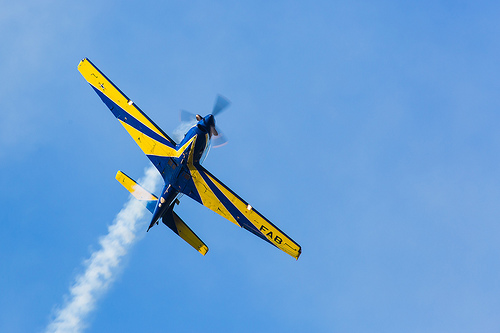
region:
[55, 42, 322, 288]
airplane in sky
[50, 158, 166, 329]
white smoke emitting from plane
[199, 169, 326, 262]
wing on plane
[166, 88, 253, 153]
propeller on front of plane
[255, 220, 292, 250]
word on plane wing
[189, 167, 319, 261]
stripes on plane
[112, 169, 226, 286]
tail of plane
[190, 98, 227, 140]
nose of plane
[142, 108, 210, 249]
body of plane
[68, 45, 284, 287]
a plane that is flying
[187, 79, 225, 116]
the blade of a propeller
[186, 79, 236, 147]
the propeller on a plane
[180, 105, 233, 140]
the nose of a plane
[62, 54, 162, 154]
the right wing of a plane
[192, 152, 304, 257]
the left wing of a plane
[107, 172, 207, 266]
the tail wing of a plane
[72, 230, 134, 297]
a bunch of white smoke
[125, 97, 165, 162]
the stripes on a plane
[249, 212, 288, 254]
the logo of a plane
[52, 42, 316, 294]
yellow and blue plane doing trick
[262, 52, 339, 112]
white clouds in blue sky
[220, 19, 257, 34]
white clouds in blue sky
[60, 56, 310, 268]
yellow and blue plane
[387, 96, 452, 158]
white clouds in blue sky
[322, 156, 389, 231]
white clouds in blue sky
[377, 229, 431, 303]
white clouds in blue sky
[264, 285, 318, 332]
white clouds in blue sky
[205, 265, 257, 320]
white clouds in blue sky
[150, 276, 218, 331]
white clouds in blue sky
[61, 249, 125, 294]
smoke from plane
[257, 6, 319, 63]
white clouds in blue sky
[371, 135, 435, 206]
white clouds in blue sky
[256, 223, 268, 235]
black letter on plane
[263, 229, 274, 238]
black letter on plane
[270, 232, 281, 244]
black letter on plane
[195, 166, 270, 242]
blue stripe on plane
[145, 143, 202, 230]
blue stripe on plane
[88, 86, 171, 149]
blue stripe on plane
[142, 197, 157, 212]
blue stripe on plane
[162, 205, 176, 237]
blue stripe on plane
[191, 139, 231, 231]
yellow stripe on plane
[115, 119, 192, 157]
yellow stripe on plane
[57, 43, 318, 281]
blue and yellow plane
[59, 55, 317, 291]
Plane in the sky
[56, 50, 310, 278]
Plane in the air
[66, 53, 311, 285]
Air plane in air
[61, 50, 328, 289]
Blue and yellow plane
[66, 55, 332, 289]
Blue and yellow air plane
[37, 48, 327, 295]
Blue and yellow plane flying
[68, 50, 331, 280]
Blue and yellow airplane flying